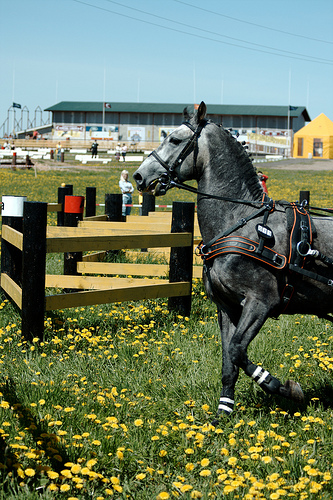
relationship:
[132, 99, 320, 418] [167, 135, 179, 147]
horse has eye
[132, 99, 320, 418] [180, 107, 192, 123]
horse has ear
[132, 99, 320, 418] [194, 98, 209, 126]
horse has ear